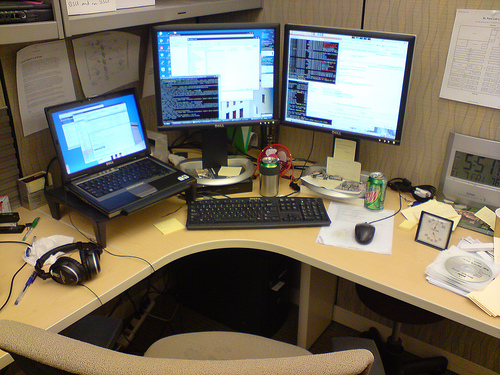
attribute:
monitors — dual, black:
[155, 21, 417, 174]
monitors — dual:
[151, 20, 417, 200]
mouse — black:
[355, 221, 376, 244]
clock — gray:
[437, 131, 498, 206]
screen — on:
[156, 32, 276, 124]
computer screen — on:
[280, 26, 414, 137]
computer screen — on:
[158, 29, 279, 122]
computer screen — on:
[53, 94, 141, 174]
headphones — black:
[34, 237, 102, 288]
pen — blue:
[12, 265, 40, 305]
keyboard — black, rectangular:
[184, 193, 332, 231]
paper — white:
[316, 194, 393, 253]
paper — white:
[418, 227, 497, 299]